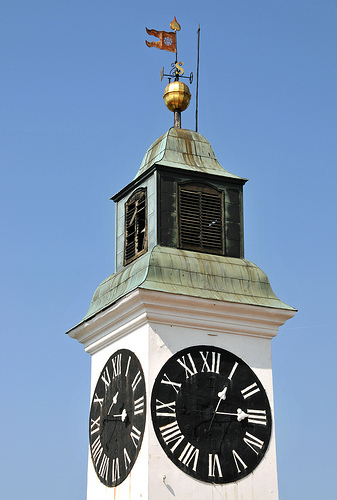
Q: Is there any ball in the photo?
A: Yes, there is a ball.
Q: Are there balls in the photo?
A: Yes, there is a ball.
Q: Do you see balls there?
A: Yes, there is a ball.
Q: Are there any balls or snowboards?
A: Yes, there is a ball.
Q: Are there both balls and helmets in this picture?
A: No, there is a ball but no helmets.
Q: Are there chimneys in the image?
A: No, there are no chimneys.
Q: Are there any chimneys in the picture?
A: No, there are no chimneys.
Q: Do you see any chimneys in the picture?
A: No, there are no chimneys.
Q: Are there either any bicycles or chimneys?
A: No, there are no chimneys or bicycles.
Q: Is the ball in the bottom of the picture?
A: No, the ball is in the top of the image.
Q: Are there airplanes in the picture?
A: No, there are no airplanes.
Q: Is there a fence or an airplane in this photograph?
A: No, there are no airplanes or fences.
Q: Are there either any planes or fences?
A: No, there are no planes or fences.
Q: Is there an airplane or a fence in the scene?
A: No, there are no airplanes or fences.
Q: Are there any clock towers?
A: Yes, there is a clock tower.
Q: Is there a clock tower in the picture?
A: Yes, there is a clock tower.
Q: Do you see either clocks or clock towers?
A: Yes, there is a clock tower.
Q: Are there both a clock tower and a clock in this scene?
A: Yes, there are both a clock tower and a clock.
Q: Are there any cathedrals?
A: No, there are no cathedrals.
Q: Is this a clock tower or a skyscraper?
A: This is a clock tower.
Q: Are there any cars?
A: No, there are no cars.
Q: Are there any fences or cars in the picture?
A: No, there are no cars or fences.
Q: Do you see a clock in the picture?
A: Yes, there is a clock.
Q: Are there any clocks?
A: Yes, there is a clock.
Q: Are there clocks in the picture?
A: Yes, there is a clock.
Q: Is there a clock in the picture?
A: Yes, there is a clock.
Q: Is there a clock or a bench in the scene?
A: Yes, there is a clock.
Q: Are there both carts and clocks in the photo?
A: No, there is a clock but no carts.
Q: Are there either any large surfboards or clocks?
A: Yes, there is a large clock.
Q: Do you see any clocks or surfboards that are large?
A: Yes, the clock is large.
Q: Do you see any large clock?
A: Yes, there is a large clock.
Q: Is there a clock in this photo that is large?
A: Yes, there is a clock that is large.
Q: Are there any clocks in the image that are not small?
A: Yes, there is a large clock.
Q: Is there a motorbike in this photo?
A: No, there are no motorcycles.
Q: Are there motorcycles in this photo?
A: No, there are no motorcycles.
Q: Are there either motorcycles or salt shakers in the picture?
A: No, there are no motorcycles or salt shakers.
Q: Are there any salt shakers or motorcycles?
A: No, there are no motorcycles or salt shakers.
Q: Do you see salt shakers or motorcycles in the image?
A: No, there are no motorcycles or salt shakers.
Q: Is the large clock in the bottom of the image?
A: Yes, the clock is in the bottom of the image.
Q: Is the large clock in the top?
A: No, the clock is in the bottom of the image.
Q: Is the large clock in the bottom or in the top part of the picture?
A: The clock is in the bottom of the image.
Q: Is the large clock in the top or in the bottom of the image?
A: The clock is in the bottom of the image.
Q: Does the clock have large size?
A: Yes, the clock is large.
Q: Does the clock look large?
A: Yes, the clock is large.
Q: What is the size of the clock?
A: The clock is large.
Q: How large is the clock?
A: The clock is large.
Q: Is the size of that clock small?
A: No, the clock is large.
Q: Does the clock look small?
A: No, the clock is large.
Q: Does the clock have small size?
A: No, the clock is large.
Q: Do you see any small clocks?
A: No, there is a clock but it is large.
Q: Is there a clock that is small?
A: No, there is a clock but it is large.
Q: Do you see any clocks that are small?
A: No, there is a clock but it is large.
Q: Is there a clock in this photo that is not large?
A: No, there is a clock but it is large.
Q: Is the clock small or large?
A: The clock is large.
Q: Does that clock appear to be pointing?
A: Yes, the clock is pointing.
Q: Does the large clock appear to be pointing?
A: Yes, the clock is pointing.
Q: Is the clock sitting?
A: No, the clock is pointing.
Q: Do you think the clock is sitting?
A: No, the clock is pointing.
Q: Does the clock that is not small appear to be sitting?
A: No, the clock is pointing.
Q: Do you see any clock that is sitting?
A: No, there is a clock but it is pointing.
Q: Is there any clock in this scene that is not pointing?
A: No, there is a clock but it is pointing.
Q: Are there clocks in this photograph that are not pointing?
A: No, there is a clock but it is pointing.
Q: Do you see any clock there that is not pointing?
A: No, there is a clock but it is pointing.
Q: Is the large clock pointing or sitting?
A: The clock is pointing.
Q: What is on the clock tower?
A: The clock is on the clock tower.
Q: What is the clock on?
A: The clock is on the clock tower.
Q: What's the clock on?
A: The clock is on the clock tower.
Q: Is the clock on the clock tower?
A: Yes, the clock is on the clock tower.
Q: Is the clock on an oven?
A: No, the clock is on the clock tower.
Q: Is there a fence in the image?
A: No, there are no fences.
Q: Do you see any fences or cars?
A: No, there are no fences or cars.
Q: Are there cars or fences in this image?
A: No, there are no fences or cars.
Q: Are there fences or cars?
A: No, there are no fences or cars.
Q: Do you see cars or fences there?
A: No, there are no fences or cars.